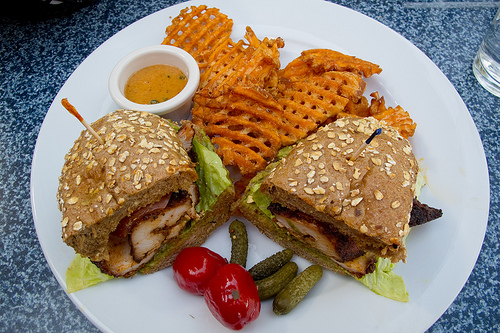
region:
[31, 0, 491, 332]
a white plate with a meal on it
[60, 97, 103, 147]
a toothpick with an orange tip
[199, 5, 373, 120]
some orange waffle fries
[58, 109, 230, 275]
half of a healthy sandwich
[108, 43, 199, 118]
a small white cup of sauce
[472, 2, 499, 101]
the bottom of a drinking glass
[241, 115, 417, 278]
a sandwich with a toothpick holding it together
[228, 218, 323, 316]
four small pickles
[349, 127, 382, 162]
a toothpick with a black tip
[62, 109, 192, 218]
whole wheat bread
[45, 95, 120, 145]
A WOODEN TOOTHPICK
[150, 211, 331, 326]
TWO TOMATOES NEXT TO FOUR PICKLES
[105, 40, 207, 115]
A CONTAINER OF SAUCE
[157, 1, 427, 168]
WAFFLE FRIES ON A WHITE PLATE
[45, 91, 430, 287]
TWO HALVES OF A SANDWICH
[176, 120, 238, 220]
SOME LETTUCE ON A SANDWICH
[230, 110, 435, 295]
ONE HALF OF A SANDWICH WITH A TOOTHPICK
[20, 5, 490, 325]
A SANDWICH AND WAFFLE FRIES ON A PLATE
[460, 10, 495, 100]
A GLASS NEXT TO A PLATE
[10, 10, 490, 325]
A PLATE OF FOOD ON A TABLE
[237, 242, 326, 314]
sweet green dill pickle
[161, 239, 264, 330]
small bright red peppers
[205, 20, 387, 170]
fried waffle fries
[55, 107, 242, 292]
a chicken sandwich with toothpick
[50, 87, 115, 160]
an orange tipped toothpick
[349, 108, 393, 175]
a blue tipped toothpick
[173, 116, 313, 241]
green lettuce from a sandwich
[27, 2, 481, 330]
a white circular plate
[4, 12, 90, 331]
a blue and white speckled table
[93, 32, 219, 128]
a yellow sauce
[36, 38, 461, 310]
white plate with food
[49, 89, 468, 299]
cut sandwich on plate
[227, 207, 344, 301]
four pickles on plate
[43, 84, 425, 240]
toothpick in top of each half of sandwich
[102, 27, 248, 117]
dipping sauce in small container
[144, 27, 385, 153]
waffle fries on plate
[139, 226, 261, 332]
red vegetable on plate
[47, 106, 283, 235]
lettuce on sandwich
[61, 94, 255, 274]
sandwich roll has seeds on top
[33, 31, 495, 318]
plate setting on blue top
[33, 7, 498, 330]
round white dinner plate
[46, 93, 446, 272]
sandwich cut in half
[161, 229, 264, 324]
two small red peppers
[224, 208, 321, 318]
four small green pickles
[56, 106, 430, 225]
multigrain bread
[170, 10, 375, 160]
orange waffle fries on back of plate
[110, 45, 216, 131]
cup with brown sauce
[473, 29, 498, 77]
bottom of water bottle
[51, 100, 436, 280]
sandwich with meat and lettuce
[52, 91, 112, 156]
toothpick with orange top